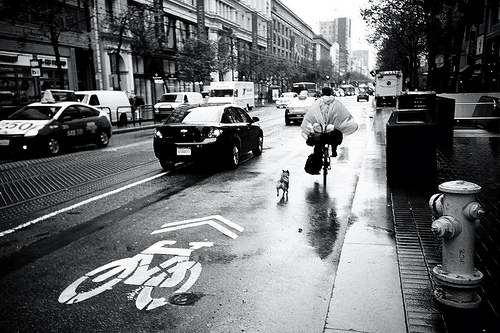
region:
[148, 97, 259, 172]
car driving down the street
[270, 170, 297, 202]
dog walking down the street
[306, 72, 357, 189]
person on a bicycle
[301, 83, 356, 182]
person wearing a white trash bag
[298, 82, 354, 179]
person wearing a white trash bag on a bicycle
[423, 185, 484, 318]
white fire hydrant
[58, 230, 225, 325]
painted shape of a bicycle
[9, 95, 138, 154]
taxi cab driving down street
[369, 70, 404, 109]
white truck driving down street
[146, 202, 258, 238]
white painted arrows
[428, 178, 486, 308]
fire hydrant on the sidewalk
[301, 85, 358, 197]
man wearing a plastic raincoat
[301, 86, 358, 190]
man on a bicycle on a wet day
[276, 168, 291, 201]
small dog chasing a bicycle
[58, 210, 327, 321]
bike lane after the rain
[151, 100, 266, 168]
black sedan on the road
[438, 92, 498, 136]
entrance to the subway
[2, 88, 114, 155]
taxi in the city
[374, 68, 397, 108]
delivery truck parked by the roadside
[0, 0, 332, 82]
row of shophouses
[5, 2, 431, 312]
a busy city street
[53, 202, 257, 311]
a bicycle lane decal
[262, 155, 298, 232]
a dog running down the street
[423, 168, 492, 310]
a fire hydrant on the sidewalk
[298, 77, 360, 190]
a man riding on a bike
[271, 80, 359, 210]
a dog running beside a bike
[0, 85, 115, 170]
a city taxi cab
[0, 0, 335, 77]
several buildings in a city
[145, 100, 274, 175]
a car driving down the street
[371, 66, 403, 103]
the back of a delivery truck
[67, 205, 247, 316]
Symbol indicating bike lane.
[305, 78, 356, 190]
Man rides bike in street.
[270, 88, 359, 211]
Dog follows bike rider.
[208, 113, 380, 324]
Street is wet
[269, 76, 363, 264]
Wet street reflects biker.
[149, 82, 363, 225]
Vehicle drives alongside biker.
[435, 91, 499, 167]
Sidewalk leads to underground.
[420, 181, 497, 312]
Fire hydrant on side of street.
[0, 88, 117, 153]
White and black car in oncoming traffic.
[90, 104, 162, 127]
Street is blocked with fences.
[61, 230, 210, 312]
A white bicycle sign on the street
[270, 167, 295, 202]
A small dog running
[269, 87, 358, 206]
A man riding a bicycle with a small dog following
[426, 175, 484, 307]
A white fire hydrant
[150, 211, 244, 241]
Two white arrows in the street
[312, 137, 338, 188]
A small bicycle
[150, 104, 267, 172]
A black car driving down the street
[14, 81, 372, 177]
A busy city street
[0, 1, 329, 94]
A row of building by the street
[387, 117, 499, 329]
A brick paved sidewalk